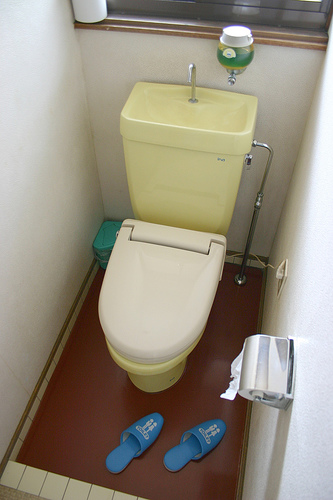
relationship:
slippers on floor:
[102, 411, 232, 475] [2, 374, 235, 500]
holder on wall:
[242, 332, 295, 406] [293, 175, 325, 405]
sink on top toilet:
[123, 63, 256, 153] [94, 82, 254, 394]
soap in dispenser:
[213, 50, 261, 70] [210, 25, 261, 86]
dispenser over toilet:
[210, 25, 261, 86] [94, 82, 254, 394]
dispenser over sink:
[210, 25, 261, 86] [123, 63, 256, 153]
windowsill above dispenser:
[122, 13, 216, 38] [210, 25, 261, 86]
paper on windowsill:
[64, 2, 126, 25] [122, 13, 216, 38]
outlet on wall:
[269, 258, 292, 297] [293, 175, 325, 405]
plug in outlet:
[273, 263, 283, 281] [269, 258, 292, 297]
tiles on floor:
[21, 464, 81, 499] [2, 374, 235, 500]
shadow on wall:
[259, 421, 294, 497] [293, 175, 325, 405]